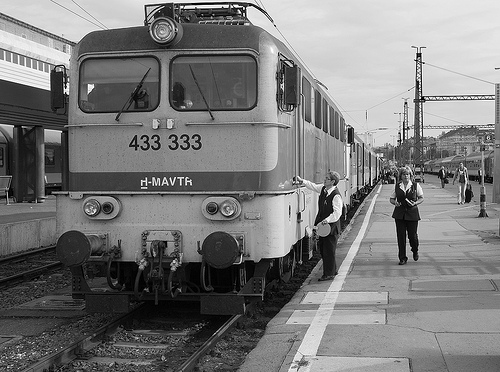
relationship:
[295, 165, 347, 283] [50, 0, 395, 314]
woman next to train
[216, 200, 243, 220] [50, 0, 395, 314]
lights on front of train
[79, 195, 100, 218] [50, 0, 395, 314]
light on front of train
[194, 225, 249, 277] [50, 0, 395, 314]
ram on train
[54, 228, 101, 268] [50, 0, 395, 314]
safety ram on train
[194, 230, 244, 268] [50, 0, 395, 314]
ram on train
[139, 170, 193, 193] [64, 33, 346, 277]
writing on front of train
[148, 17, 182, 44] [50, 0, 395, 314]
light on top of train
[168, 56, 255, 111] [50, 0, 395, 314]
frontwindow on train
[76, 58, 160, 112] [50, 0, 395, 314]
frontwindow on train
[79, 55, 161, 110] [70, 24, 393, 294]
windshield on train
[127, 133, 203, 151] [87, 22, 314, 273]
numbers on train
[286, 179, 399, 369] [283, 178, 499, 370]
white line on platform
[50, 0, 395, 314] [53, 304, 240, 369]
train on track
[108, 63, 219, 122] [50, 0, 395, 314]
wipers on train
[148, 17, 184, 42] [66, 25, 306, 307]
light on train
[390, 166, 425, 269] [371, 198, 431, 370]
person walking on sidewalk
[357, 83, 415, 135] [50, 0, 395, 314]
power lines over train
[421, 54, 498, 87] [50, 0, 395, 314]
power lines over train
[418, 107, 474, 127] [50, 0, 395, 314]
power lines over train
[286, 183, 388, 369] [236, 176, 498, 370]
white line on edge of platform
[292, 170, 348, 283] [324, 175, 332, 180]
woman wearing glasses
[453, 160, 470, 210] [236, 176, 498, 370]
person walking on platform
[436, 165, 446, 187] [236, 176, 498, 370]
person walking on platform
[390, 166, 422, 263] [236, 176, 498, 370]
person walking on platform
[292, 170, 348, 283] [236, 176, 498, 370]
woman walking on platform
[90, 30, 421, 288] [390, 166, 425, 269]
train has person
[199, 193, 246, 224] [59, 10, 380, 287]
lights on front of train